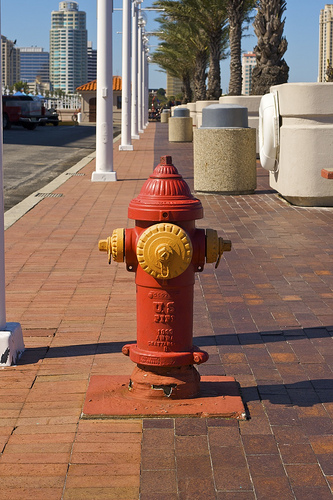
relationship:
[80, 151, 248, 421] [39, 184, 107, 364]
fire hydrant in sidewalk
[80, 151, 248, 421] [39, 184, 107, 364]
fire hydrant on sidewalk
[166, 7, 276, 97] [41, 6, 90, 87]
tree near building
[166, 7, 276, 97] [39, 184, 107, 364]
tree on sidewalk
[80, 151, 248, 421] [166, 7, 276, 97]
fire hydrant near tree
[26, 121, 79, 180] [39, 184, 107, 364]
road near sidewalk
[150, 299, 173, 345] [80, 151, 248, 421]
text on fire hydrant